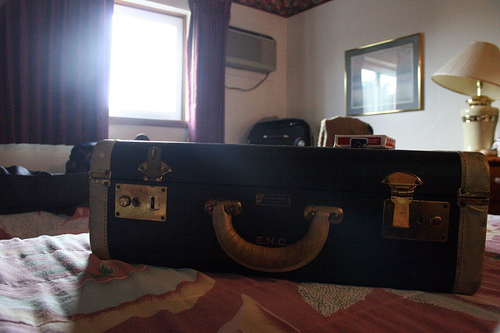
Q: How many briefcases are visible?
A: One.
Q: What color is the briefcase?
A: Black.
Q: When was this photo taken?
A: Inside, during the daytime.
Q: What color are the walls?
A: White.